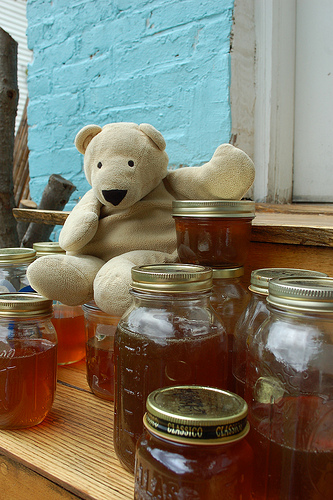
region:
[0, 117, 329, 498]
a teddy bear with jars of honey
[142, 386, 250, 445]
the jar lid says classico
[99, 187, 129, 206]
the bear's nose is triangular shaped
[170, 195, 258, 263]
the jar of honey is smaller than the rest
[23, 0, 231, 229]
the brick wall is blue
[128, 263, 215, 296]
the jar lid is golden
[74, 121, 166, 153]
the bear has ears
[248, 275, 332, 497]
the honey jar is half full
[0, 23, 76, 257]
cut off tree branches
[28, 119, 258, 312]
the bear is tan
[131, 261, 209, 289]
cap on the jar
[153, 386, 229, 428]
lid on the jar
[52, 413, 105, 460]
wood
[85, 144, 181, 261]
a brown teddy bear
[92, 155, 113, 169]
the eye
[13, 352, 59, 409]
liquid in a jar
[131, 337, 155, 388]
dark liquid in the jar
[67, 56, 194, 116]
a blue brick building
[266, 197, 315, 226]
wood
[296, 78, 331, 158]
a white door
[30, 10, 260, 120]
blue and white concrete wall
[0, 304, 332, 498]
honey filled mason jars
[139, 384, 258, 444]
golden Classico labeled jar lid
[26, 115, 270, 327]
teddy bear sitting on honey jars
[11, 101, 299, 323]
teddy bear surrounded by honey jars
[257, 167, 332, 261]
wooden door step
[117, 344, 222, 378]
freshly jarred brown honey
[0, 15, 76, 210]
trimmed dark brown tree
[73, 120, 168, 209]
light brown teddy bear face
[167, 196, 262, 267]
short clear mason jar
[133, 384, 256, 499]
A glass jar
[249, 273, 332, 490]
A tall glass jar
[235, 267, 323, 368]
A glass jar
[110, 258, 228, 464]
A large glass jar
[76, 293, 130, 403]
A small glass jar under the stuffed animal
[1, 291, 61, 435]
A glass jar on the table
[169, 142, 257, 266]
A small glass jar under the teddy's arm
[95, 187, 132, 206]
The nose of the teddy bear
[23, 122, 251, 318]
A brown teddy bear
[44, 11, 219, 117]
A light green bricked wall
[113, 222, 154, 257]
the bear is tan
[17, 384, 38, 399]
the liquid is amber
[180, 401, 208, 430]
the lid is gold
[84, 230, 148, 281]
the bear is sitting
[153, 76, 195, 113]
the building is blue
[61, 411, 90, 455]
the table is brown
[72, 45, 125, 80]
the building is made of bricks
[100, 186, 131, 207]
the nose is black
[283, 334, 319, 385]
the glass is clear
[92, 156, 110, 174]
the eye is black